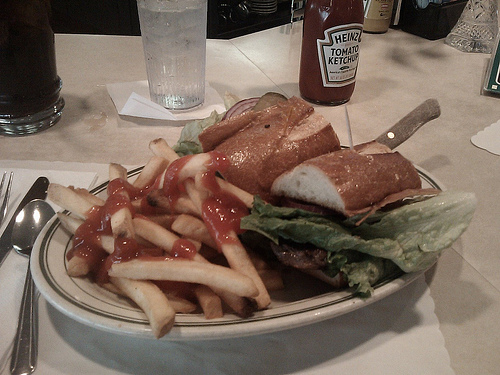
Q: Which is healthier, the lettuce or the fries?
A: The lettuce is healthier than the fries.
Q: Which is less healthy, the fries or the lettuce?
A: The fries is less healthy than the lettuce.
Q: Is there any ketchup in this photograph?
A: Yes, there is ketchup.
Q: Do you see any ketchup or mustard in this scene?
A: Yes, there is ketchup.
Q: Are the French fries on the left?
A: Yes, the French fries are on the left of the image.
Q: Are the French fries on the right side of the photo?
A: No, the French fries are on the left of the image.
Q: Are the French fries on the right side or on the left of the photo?
A: The French fries are on the left of the image.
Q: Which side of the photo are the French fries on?
A: The French fries are on the left of the image.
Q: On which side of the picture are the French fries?
A: The French fries are on the left of the image.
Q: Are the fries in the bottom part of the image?
A: Yes, the fries are in the bottom of the image.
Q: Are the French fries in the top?
A: No, the French fries are in the bottom of the image.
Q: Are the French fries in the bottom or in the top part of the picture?
A: The French fries are in the bottom of the image.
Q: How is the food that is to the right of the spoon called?
A: The food is fries.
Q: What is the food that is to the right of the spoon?
A: The food is fries.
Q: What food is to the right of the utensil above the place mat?
A: The food is fries.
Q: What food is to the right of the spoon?
A: The food is fries.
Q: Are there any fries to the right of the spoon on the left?
A: Yes, there are fries to the right of the spoon.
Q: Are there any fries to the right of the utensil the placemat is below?
A: Yes, there are fries to the right of the spoon.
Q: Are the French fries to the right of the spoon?
A: Yes, the French fries are to the right of the spoon.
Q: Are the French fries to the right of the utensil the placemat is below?
A: Yes, the French fries are to the right of the spoon.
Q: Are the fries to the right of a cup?
A: No, the fries are to the right of the spoon.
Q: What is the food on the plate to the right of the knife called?
A: The food is fries.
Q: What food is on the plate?
A: The food is fries.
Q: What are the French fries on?
A: The French fries are on the plate.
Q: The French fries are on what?
A: The French fries are on the plate.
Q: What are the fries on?
A: The French fries are on the plate.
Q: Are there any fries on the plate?
A: Yes, there are fries on the plate.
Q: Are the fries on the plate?
A: Yes, the fries are on the plate.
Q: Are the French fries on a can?
A: No, the French fries are on the plate.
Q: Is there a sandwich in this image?
A: Yes, there is a sandwich.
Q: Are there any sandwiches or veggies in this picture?
A: Yes, there is a sandwich.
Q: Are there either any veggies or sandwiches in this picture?
A: Yes, there is a sandwich.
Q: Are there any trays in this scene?
A: No, there are no trays.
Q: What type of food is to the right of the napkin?
A: The food is a sandwich.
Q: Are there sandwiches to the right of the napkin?
A: Yes, there is a sandwich to the right of the napkin.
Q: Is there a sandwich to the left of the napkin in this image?
A: No, the sandwich is to the right of the napkin.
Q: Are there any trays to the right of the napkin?
A: No, there is a sandwich to the right of the napkin.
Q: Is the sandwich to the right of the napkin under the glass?
A: Yes, the sandwich is to the right of the napkin.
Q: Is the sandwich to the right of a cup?
A: No, the sandwich is to the right of the napkin.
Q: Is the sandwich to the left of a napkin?
A: No, the sandwich is to the right of a napkin.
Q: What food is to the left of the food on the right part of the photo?
A: The food is a sandwich.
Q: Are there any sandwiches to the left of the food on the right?
A: Yes, there is a sandwich to the left of the food.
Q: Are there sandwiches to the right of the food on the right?
A: No, the sandwich is to the left of the food.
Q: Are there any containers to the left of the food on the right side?
A: No, there is a sandwich to the left of the food.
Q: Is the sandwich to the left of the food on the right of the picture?
A: Yes, the sandwich is to the left of the food.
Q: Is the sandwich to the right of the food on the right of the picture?
A: No, the sandwich is to the left of the food.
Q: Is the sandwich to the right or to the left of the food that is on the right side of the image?
A: The sandwich is to the left of the food.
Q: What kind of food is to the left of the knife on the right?
A: The food is a sandwich.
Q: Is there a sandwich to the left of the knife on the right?
A: Yes, there is a sandwich to the left of the knife.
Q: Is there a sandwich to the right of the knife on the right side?
A: No, the sandwich is to the left of the knife.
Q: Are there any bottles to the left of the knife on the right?
A: No, there is a sandwich to the left of the knife.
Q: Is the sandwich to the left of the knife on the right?
A: Yes, the sandwich is to the left of the knife.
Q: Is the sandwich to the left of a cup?
A: No, the sandwich is to the left of the knife.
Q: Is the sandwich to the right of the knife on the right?
A: No, the sandwich is to the left of the knife.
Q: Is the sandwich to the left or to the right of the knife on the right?
A: The sandwich is to the left of the knife.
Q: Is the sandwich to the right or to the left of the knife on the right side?
A: The sandwich is to the left of the knife.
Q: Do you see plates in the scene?
A: Yes, there is a plate.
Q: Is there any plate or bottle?
A: Yes, there is a plate.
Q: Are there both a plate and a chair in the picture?
A: No, there is a plate but no chairs.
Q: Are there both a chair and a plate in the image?
A: No, there is a plate but no chairs.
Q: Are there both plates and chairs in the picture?
A: No, there is a plate but no chairs.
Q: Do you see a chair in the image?
A: No, there are no chairs.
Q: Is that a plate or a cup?
A: That is a plate.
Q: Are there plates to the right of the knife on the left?
A: Yes, there is a plate to the right of the knife.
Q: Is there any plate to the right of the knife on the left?
A: Yes, there is a plate to the right of the knife.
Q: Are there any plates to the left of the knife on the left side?
A: No, the plate is to the right of the knife.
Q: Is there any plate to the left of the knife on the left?
A: No, the plate is to the right of the knife.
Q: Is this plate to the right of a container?
A: No, the plate is to the right of the knife.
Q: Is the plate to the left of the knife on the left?
A: No, the plate is to the right of the knife.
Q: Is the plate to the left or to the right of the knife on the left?
A: The plate is to the right of the knife.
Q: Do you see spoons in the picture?
A: Yes, there is a spoon.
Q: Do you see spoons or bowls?
A: Yes, there is a spoon.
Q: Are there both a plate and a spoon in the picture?
A: Yes, there are both a spoon and a plate.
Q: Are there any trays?
A: No, there are no trays.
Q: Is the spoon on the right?
A: No, the spoon is on the left of the image.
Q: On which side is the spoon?
A: The spoon is on the left of the image.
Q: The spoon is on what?
A: The spoon is on the table.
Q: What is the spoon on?
A: The spoon is on the table.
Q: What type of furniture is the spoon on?
A: The spoon is on the table.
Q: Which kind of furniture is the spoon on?
A: The spoon is on the table.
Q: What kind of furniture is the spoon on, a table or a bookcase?
A: The spoon is on a table.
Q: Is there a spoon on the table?
A: Yes, there is a spoon on the table.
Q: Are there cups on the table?
A: No, there is a spoon on the table.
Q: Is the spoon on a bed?
A: No, the spoon is on the table.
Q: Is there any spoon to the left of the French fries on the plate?
A: Yes, there is a spoon to the left of the French fries.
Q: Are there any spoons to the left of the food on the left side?
A: Yes, there is a spoon to the left of the French fries.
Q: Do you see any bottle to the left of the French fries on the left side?
A: No, there is a spoon to the left of the fries.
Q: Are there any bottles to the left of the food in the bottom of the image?
A: No, there is a spoon to the left of the fries.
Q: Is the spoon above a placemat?
A: Yes, the spoon is above a placemat.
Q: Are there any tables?
A: Yes, there is a table.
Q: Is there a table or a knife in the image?
A: Yes, there is a table.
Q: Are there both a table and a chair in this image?
A: No, there is a table but no chairs.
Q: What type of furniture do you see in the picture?
A: The furniture is a table.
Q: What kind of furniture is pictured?
A: The furniture is a table.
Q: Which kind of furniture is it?
A: The piece of furniture is a table.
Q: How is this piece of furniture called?
A: This is a table.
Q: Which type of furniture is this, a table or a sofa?
A: This is a table.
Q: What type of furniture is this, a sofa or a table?
A: This is a table.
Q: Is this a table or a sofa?
A: This is a table.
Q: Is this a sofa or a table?
A: This is a table.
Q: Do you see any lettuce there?
A: Yes, there is lettuce.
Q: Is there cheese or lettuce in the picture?
A: Yes, there is lettuce.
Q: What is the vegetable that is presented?
A: The vegetable is lettuce.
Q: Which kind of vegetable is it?
A: The vegetable is lettuce.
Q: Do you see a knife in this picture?
A: Yes, there is a knife.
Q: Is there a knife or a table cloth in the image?
A: Yes, there is a knife.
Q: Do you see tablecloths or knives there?
A: Yes, there is a knife.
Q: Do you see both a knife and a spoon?
A: Yes, there are both a knife and a spoon.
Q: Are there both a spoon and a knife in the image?
A: Yes, there are both a knife and a spoon.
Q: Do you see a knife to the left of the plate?
A: Yes, there is a knife to the left of the plate.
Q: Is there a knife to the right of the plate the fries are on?
A: No, the knife is to the left of the plate.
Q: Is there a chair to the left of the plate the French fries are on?
A: No, there is a knife to the left of the plate.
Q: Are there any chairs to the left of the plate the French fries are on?
A: No, there is a knife to the left of the plate.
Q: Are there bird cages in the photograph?
A: No, there are no bird cages.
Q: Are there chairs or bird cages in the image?
A: No, there are no bird cages or chairs.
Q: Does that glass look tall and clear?
A: Yes, the glass is tall and clear.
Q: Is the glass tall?
A: Yes, the glass is tall.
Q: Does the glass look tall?
A: Yes, the glass is tall.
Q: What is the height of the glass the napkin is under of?
A: The glass is tall.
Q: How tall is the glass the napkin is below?
A: The glass is tall.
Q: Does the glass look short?
A: No, the glass is tall.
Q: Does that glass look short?
A: No, the glass is tall.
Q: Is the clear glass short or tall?
A: The glass is tall.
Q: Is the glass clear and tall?
A: Yes, the glass is clear and tall.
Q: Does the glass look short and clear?
A: No, the glass is clear but tall.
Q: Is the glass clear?
A: Yes, the glass is clear.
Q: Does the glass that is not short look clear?
A: Yes, the glass is clear.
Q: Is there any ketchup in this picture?
A: Yes, there is ketchup.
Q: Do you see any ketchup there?
A: Yes, there is ketchup.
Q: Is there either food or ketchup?
A: Yes, there is ketchup.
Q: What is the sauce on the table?
A: The sauce is ketchup.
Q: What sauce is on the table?
A: The sauce is ketchup.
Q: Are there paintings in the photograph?
A: No, there are no paintings.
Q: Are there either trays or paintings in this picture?
A: No, there are no paintings or trays.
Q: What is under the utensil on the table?
A: The place mat is under the spoon.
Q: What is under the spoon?
A: The place mat is under the spoon.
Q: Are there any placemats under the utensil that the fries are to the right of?
A: Yes, there is a placemat under the spoon.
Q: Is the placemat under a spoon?
A: Yes, the placemat is under a spoon.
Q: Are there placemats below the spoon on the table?
A: Yes, there is a placemat below the spoon.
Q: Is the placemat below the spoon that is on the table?
A: Yes, the placemat is below the spoon.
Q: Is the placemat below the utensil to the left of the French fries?
A: Yes, the placemat is below the spoon.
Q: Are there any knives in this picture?
A: Yes, there is a knife.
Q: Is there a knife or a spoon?
A: Yes, there is a knife.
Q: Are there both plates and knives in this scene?
A: Yes, there are both a knife and a plate.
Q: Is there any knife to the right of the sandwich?
A: Yes, there is a knife to the right of the sandwich.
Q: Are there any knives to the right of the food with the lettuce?
A: Yes, there is a knife to the right of the sandwich.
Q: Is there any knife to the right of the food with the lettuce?
A: Yes, there is a knife to the right of the sandwich.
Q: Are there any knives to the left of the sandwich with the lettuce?
A: No, the knife is to the right of the sandwich.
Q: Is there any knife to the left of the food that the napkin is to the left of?
A: No, the knife is to the right of the sandwich.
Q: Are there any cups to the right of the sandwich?
A: No, there is a knife to the right of the sandwich.